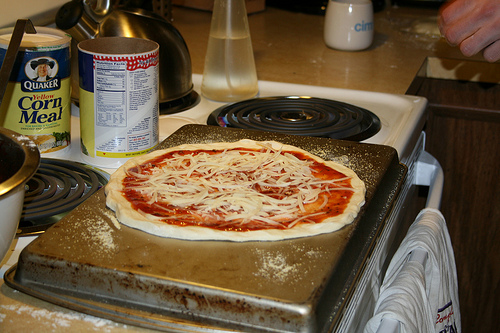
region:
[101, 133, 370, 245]
A prepared homemade cheese pizza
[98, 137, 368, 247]
Pizza sitting on bottom of pan.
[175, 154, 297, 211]
Shredded cheese on top of pizza.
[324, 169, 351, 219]
Tomato sauce on top of pizza.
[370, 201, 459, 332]
Dish towel over oven handle.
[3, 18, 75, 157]
Box of corn meal sitting on stove.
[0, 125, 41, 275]
Edge of bowl sitting on stove.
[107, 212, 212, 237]
Edge of pizza crust.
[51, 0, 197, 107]
Silver kettle sitting on stove burner.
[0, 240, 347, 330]
Bottom edge of pan pizza sitting on.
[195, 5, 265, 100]
Bottle with clear liquid sitting on stove.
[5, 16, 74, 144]
The can of corn meal.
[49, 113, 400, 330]
The baking pan.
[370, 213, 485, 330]
The towel hanging on the oven door.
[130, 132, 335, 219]
The shredded cheese on the pizza.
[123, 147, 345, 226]
The red sauce on the pizza.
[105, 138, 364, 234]
The dough of the pizza.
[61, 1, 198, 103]
The tea kettle on the stove.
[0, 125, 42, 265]
The bowl on the left.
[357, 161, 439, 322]
The handle of the oven.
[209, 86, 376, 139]
The burner on the right.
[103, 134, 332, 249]
SMALL PIZZA ON PAN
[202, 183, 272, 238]
RED TOMATO SAUCE ON PAN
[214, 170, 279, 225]
UNMELTED CHEESE ON PIZZA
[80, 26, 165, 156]
SMALL CONTAINER ON OVEN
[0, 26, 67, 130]
SMALL CONTAINER ON OVEN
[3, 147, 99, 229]
BLACK BURNER ON STOVE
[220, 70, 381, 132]
BLACK BURNER ON STOVE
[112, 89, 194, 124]
BLACK BURNER ON STOVE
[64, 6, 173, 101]
METAL TEAPOT ON STOVE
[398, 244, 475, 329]
WHITE SHIRT ON FRONT OF STOVE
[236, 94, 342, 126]
black burner on stove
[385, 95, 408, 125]
white color on the stove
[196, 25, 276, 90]
clear bottle with straw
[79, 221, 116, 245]
flour on top of surface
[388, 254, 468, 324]
white kitchen towel on stove handle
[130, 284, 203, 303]
burnt edge of surface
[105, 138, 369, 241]
white pie on top of surface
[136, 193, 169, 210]
red sauce on pizza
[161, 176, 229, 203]
white cheese on top of pizza